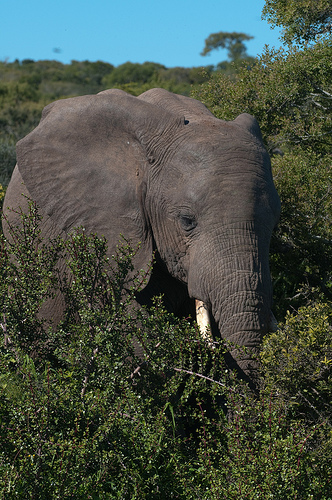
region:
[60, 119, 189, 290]
An elephant is visible.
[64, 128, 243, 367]
An elephant is visible.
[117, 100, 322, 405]
An elephant is visible.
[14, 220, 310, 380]
An elephant is visible.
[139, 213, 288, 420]
An elephant is visible.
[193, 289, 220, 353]
elephant's white tusk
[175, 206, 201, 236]
open elephant's right eye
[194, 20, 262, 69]
tree silhouette against sky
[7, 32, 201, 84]
tree tops against blue sky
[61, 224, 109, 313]
plant with green leaves and red stems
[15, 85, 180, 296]
gray elephant's right ear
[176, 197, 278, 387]
elephant's eye, trunk and tusk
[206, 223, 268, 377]
wrinkled elephant trunk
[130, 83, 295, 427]
elephant in forest brush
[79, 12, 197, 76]
blue sky without clouds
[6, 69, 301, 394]
large grey elephant in bushes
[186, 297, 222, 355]
ivory tusk on elephant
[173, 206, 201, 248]
eye on side of elephant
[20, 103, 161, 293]
large ear on elephant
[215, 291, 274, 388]
part of elephant trunk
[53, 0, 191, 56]
bright clear blue sky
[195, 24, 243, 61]
green tree standing in background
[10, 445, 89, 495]
patch of green bushes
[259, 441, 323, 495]
patch of green bushes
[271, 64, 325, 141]
part of green trees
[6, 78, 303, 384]
Gray elephant in trees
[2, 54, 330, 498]
Green bushes surround elephant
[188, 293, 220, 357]
Elephant has white tusk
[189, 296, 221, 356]
Tusk is made from ivory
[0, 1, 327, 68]
Sky is clear and blue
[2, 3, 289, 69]
Sky is blue and clear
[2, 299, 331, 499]
Leaves are green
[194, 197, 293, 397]
Elephant trunk is wrinkly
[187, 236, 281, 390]
Elephant trunk is gray and wrinkly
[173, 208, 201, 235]
Elephant's eye is dark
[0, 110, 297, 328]
a elephant standing in bushes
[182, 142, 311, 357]
a elephant with white tusks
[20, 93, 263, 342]
a elephant with a large ear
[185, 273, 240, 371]
a white elephant tusks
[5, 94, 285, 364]
a large elephant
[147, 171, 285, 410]
a elephant with its trunk down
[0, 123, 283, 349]
a grey elephant standing in bushes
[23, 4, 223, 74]
a clear blue sky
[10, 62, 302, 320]
an elephant in a field of bushes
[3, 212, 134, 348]
green bushes with red leaves